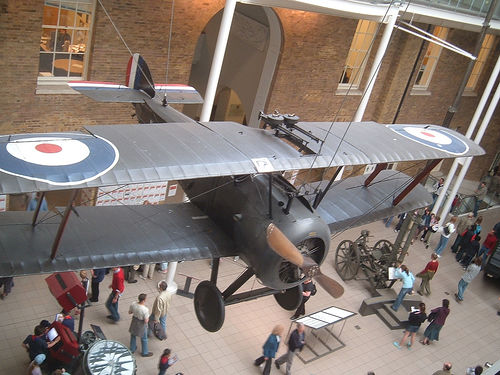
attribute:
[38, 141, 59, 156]
dots — red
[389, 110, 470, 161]
target — white